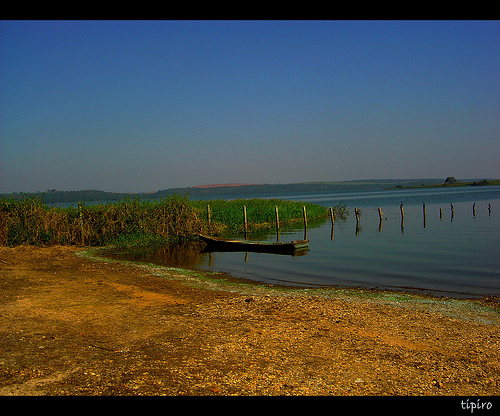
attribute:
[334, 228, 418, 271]
water — blue, close, reflecting, still, large, rippled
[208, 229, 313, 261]
boat — empty, green, smaller, alone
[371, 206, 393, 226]
stump — brown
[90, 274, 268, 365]
shore — dirty, tan, rocky, brown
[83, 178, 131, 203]
mountians — far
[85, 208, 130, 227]
shrubs — green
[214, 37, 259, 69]
sky — clear, blue